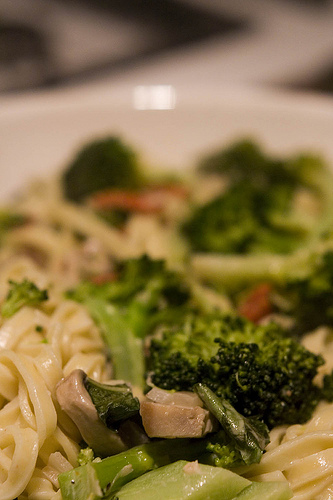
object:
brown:
[139, 382, 212, 441]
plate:
[0, 82, 331, 197]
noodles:
[2, 175, 183, 285]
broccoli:
[181, 173, 308, 298]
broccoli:
[151, 313, 321, 429]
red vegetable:
[235, 283, 274, 325]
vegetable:
[69, 173, 322, 426]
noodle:
[276, 432, 323, 452]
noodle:
[312, 408, 331, 432]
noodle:
[295, 486, 316, 498]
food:
[0, 133, 333, 496]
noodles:
[0, 299, 98, 500]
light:
[128, 81, 183, 110]